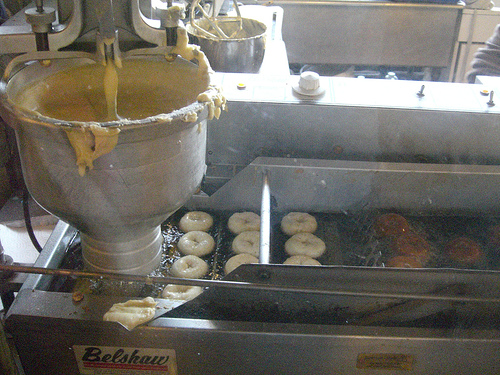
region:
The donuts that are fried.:
[370, 204, 498, 265]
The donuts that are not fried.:
[180, 208, 323, 277]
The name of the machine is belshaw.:
[67, 342, 171, 373]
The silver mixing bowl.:
[5, 105, 231, 257]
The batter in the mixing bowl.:
[18, 96, 243, 133]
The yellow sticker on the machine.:
[351, 350, 409, 372]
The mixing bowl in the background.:
[186, 15, 276, 65]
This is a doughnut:
[374, 210, 410, 235]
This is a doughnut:
[391, 232, 438, 255]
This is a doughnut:
[384, 255, 432, 274]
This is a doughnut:
[441, 232, 484, 268]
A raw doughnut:
[276, 207, 319, 232]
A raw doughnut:
[280, 229, 332, 254]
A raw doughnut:
[280, 252, 337, 277]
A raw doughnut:
[225, 206, 266, 231]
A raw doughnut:
[227, 228, 275, 256]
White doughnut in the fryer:
[180, 207, 215, 233]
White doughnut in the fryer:
[178, 229, 214, 256]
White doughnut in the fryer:
[167, 252, 208, 284]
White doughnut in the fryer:
[160, 278, 200, 300]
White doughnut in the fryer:
[225, 206, 262, 231]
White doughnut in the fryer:
[228, 226, 261, 249]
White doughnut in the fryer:
[222, 250, 257, 271]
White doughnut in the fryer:
[278, 205, 319, 232]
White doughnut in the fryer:
[280, 235, 329, 255]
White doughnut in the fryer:
[282, 250, 325, 270]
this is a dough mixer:
[6, 56, 229, 268]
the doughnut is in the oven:
[438, 225, 493, 270]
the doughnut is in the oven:
[394, 225, 434, 267]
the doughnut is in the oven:
[376, 241, 423, 278]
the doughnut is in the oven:
[284, 196, 322, 236]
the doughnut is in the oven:
[279, 224, 332, 266]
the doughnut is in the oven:
[289, 247, 331, 283]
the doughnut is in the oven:
[214, 253, 256, 289]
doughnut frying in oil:
[376, 209, 406, 235]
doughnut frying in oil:
[392, 233, 431, 258]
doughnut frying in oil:
[444, 235, 481, 264]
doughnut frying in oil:
[386, 255, 421, 269]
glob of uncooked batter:
[103, 295, 156, 327]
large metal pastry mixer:
[189, 0, 240, 38]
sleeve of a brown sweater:
[465, 24, 499, 82]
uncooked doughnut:
[168, 255, 209, 280]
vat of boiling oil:
[46, 204, 498, 298]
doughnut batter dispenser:
[0, 0, 222, 283]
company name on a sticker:
[71, 339, 181, 374]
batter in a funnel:
[18, 61, 208, 131]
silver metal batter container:
[3, 54, 213, 277]